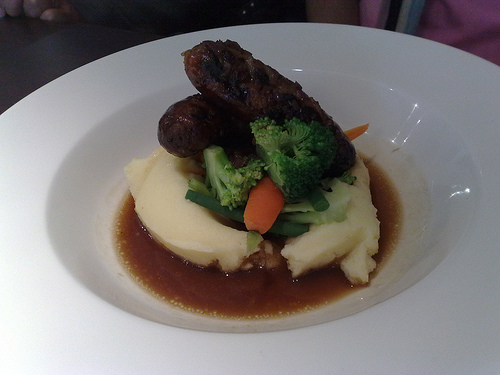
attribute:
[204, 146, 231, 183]
stem — cut 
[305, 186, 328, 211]
bean — cut 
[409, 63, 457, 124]
plate — white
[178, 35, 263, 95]
sausage — cooked 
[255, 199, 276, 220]
carrot — orange, cooked 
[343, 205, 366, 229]
mashed potatoes — white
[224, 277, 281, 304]
gravy — brown